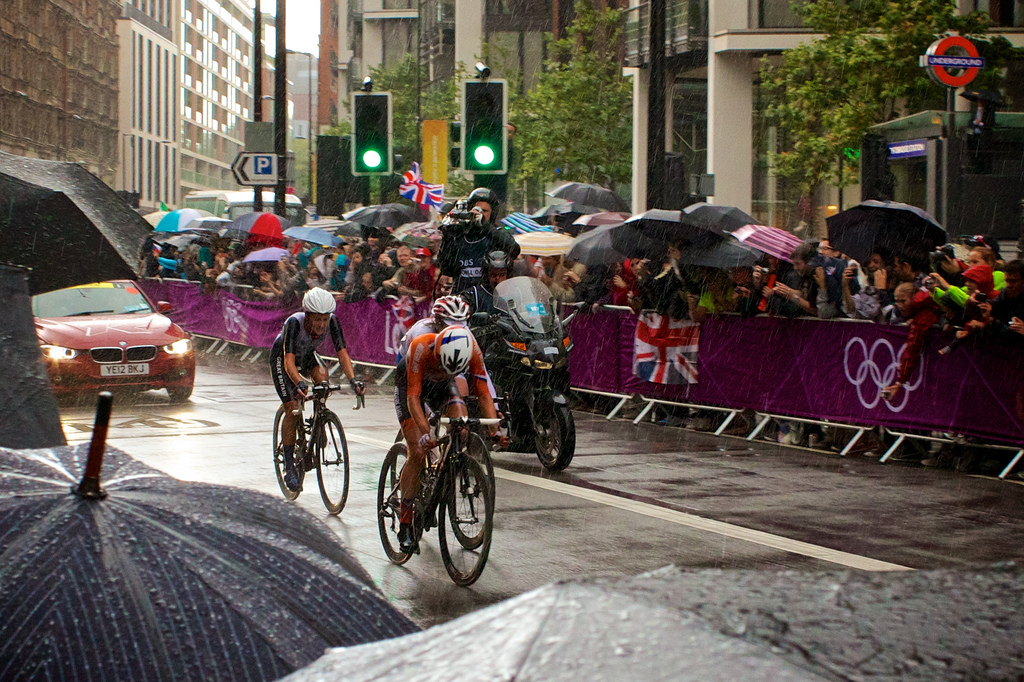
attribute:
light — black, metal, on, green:
[343, 92, 412, 192]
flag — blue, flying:
[398, 172, 467, 211]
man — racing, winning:
[403, 321, 501, 432]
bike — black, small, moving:
[396, 437, 512, 546]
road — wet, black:
[603, 434, 745, 544]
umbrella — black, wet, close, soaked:
[35, 421, 280, 657]